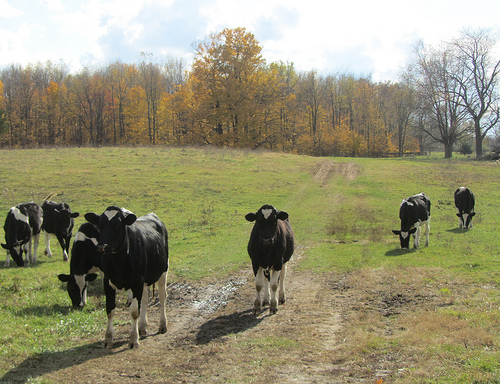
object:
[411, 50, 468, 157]
tree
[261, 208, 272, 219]
spot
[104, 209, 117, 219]
spot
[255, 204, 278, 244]
face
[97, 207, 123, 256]
face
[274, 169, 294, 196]
green grass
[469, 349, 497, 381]
grass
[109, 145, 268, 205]
grass pasture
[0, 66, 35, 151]
trees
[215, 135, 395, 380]
passage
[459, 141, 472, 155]
small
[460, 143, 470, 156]
green tree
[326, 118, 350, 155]
tree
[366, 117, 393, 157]
tree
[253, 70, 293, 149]
tree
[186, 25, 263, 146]
tree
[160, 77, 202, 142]
tree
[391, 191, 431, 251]
cow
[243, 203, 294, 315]
cow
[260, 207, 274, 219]
triangle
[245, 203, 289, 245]
head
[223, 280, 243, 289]
puddle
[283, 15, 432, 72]
sky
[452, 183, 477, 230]
cows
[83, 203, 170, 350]
cows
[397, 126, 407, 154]
baseball bat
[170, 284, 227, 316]
mud pool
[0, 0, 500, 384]
outdoors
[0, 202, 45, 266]
cow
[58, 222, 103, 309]
cow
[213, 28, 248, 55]
leaves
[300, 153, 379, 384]
tracks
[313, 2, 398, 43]
clouds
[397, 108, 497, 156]
distance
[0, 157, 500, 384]
field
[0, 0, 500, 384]
picture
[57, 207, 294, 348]
walking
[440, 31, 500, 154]
tree